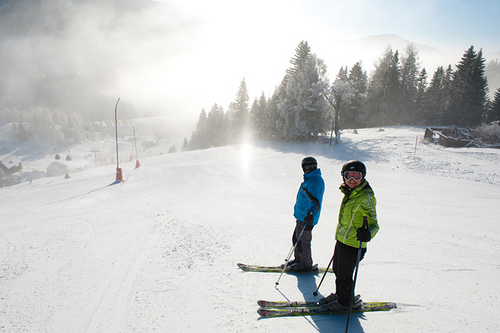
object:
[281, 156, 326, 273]
skier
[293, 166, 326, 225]
jacket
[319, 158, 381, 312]
skier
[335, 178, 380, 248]
jacket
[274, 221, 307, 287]
ski pole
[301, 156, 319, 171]
cap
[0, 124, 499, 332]
snow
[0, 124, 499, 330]
ground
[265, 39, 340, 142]
pine tree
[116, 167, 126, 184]
cone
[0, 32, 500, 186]
mountain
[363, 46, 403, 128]
tree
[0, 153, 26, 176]
house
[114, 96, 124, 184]
pole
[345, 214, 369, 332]
ski pole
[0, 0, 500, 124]
cloud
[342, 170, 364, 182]
ski goggles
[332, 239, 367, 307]
pants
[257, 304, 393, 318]
snow ski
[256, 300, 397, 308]
snow ski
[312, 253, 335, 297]
ski pole